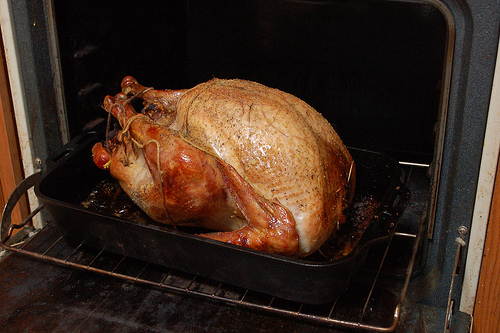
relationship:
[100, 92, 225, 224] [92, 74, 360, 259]
legs are on turkey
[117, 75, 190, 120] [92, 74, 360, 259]
legs are on turkey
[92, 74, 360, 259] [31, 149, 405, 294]
turkey in pan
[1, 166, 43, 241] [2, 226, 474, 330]
hinge on oven door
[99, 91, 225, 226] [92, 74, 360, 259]
drumstick on turkey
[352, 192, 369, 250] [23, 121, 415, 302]
drippings are in pan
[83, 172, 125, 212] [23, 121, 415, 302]
drippings are in pan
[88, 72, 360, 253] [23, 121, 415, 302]
poultry in pan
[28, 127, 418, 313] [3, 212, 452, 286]
roasting pan on rack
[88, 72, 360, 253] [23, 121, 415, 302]
poultry on a pan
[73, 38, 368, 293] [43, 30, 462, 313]
chicken in an oven